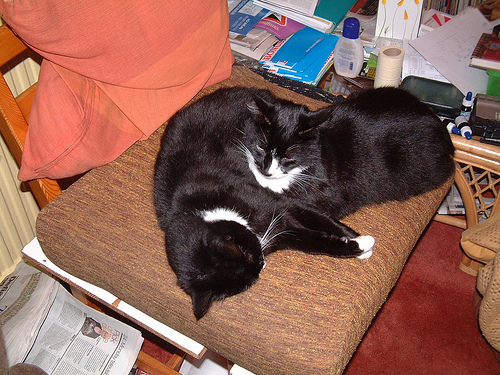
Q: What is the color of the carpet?
A: Red.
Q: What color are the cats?
A: Black.